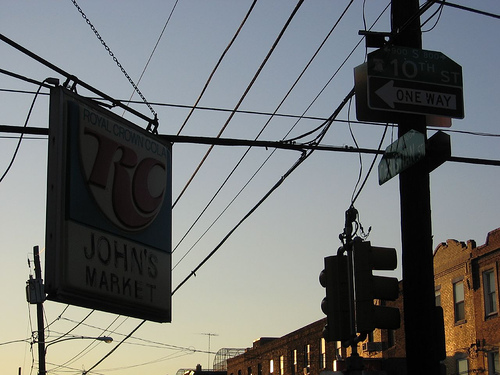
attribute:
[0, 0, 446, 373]
utility lines — strung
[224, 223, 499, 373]
building — bright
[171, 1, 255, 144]
wire — criss crossing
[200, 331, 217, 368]
antenna — mounted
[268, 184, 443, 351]
streetlight — protruding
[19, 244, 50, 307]
transformer — hanging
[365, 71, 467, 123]
sign — oneway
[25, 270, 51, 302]
box — electrical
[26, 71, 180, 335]
sign — worn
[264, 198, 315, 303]
sky — blue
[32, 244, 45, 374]
post — holding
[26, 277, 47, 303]
equipment — utility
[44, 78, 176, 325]
advertising sign — hanging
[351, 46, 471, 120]
sign — one way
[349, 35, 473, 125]
sign — white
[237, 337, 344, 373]
windows — darkened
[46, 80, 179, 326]
sign — hanging, unreadable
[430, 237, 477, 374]
building — old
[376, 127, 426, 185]
street sign — unreadable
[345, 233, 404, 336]
traffic light — black , hanging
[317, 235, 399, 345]
traffic light — facing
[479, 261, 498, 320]
window — vertical